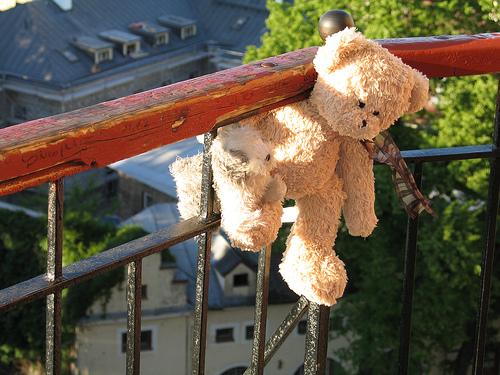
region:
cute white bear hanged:
[215, 60, 425, 361]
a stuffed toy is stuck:
[216, 75, 302, 209]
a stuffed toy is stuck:
[226, 71, 329, 316]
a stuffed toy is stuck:
[232, 105, 295, 282]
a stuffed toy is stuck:
[304, 200, 358, 337]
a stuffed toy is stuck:
[211, 152, 309, 362]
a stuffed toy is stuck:
[262, 95, 382, 357]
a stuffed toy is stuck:
[274, 152, 343, 326]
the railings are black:
[43, 147, 312, 372]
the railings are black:
[159, 247, 314, 373]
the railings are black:
[211, 308, 268, 361]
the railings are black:
[142, 272, 262, 367]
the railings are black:
[397, 297, 474, 361]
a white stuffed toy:
[241, 88, 299, 202]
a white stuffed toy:
[281, 47, 331, 194]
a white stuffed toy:
[228, 49, 386, 213]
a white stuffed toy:
[181, 109, 360, 251]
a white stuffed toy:
[285, 116, 396, 248]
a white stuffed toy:
[224, 177, 341, 301]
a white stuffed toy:
[262, 142, 444, 354]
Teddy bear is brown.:
[297, 137, 350, 167]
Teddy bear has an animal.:
[218, 121, 283, 168]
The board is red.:
[127, 124, 158, 155]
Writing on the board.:
[18, 139, 95, 170]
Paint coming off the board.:
[147, 100, 200, 135]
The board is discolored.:
[57, 101, 122, 133]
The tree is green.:
[416, 78, 486, 123]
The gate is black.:
[411, 138, 490, 178]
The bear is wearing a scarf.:
[366, 142, 406, 171]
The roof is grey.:
[60, 0, 168, 32]